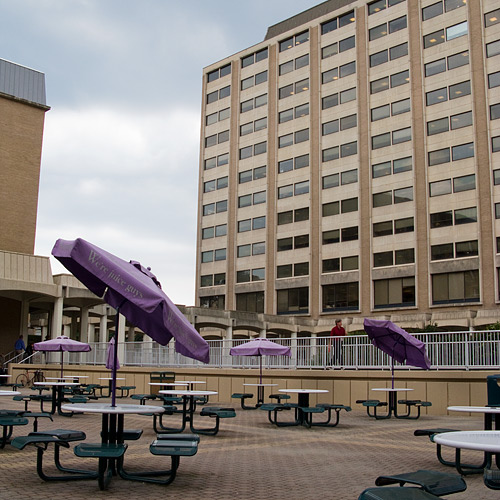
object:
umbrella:
[51, 236, 211, 407]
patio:
[0, 388, 497, 500]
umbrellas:
[32, 334, 92, 378]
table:
[58, 402, 166, 414]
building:
[193, 0, 500, 340]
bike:
[16, 368, 46, 389]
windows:
[430, 268, 481, 306]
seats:
[120, 439, 199, 486]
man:
[329, 318, 348, 370]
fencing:
[45, 329, 499, 370]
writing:
[87, 249, 143, 298]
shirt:
[330, 326, 346, 342]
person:
[23, 341, 34, 364]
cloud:
[42, 11, 149, 77]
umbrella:
[104, 335, 120, 370]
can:
[149, 370, 176, 402]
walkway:
[47, 363, 500, 371]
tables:
[431, 429, 499, 454]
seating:
[0, 383, 500, 499]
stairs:
[0, 347, 40, 384]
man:
[14, 334, 27, 363]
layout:
[0, 374, 500, 500]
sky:
[0, 0, 329, 307]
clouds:
[153, 11, 231, 64]